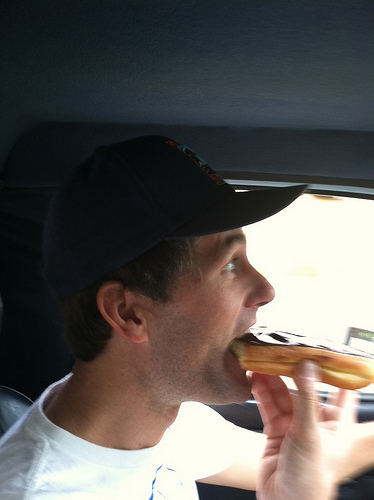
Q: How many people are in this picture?
A: One.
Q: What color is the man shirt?
A: White.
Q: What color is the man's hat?
A: Black.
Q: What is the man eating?
A: An eclair.